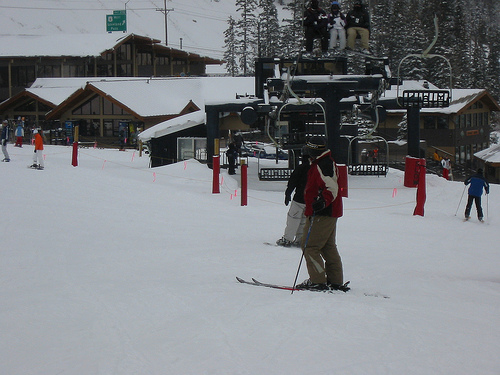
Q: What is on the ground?
A: Snow.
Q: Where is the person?
A: A ski lift.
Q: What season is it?
A: Winter.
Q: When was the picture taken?
A: Winter.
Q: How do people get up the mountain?
A: A chair lift.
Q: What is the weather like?
A: Cold and snowy.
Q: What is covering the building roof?
A: Snow.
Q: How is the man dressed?
A: Jacket and snowpants.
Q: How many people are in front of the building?
A: Three.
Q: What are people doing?
A: Skiing.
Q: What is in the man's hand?
A: Ski pole.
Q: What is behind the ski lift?
A: Building.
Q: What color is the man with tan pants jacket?
A: Red, white and black.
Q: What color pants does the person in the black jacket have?
A: Grey.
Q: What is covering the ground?
A: Snow.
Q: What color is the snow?
A: White.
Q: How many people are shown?
A: 5.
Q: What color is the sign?
A: Green.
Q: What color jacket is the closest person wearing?
A: Red.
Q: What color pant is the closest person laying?
A: Khaki.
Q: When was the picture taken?
A: Evening.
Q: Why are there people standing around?
A: They are waiting to ski.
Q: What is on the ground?
A: Snow.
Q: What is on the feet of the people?
A: Skis.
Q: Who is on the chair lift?
A: Skiers.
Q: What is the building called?
A: Lodge.